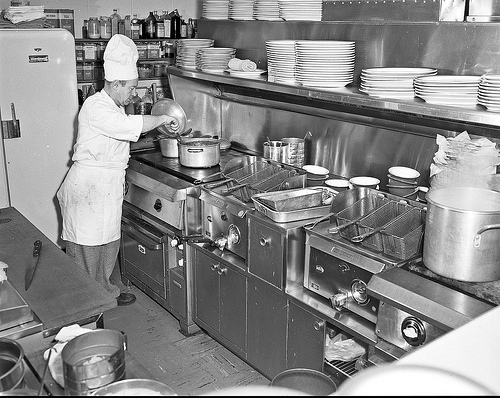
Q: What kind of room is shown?
A: It is a kitchen.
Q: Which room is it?
A: It is a kitchen.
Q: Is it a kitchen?
A: Yes, it is a kitchen.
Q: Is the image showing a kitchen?
A: Yes, it is showing a kitchen.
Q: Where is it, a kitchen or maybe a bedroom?
A: It is a kitchen.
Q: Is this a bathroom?
A: No, it is a kitchen.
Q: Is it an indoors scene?
A: Yes, it is indoors.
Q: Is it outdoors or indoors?
A: It is indoors.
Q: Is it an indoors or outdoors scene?
A: It is indoors.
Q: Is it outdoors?
A: No, it is indoors.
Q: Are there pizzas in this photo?
A: No, there are no pizzas.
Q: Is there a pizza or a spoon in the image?
A: No, there are no pizzas or spoons.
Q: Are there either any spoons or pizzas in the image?
A: No, there are no pizzas or spoons.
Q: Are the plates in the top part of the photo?
A: Yes, the plates are in the top of the image.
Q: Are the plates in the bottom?
A: No, the plates are in the top of the image.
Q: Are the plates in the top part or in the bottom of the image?
A: The plates are in the top of the image.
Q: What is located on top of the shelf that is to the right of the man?
A: The plates are on top of the shelf.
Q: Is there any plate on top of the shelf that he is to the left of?
A: Yes, there are plates on top of the shelf.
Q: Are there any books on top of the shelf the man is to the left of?
A: No, there are plates on top of the shelf.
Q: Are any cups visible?
A: No, there are no cups.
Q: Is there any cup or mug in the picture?
A: No, there are no cups or mugs.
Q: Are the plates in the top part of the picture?
A: Yes, the plates are in the top of the image.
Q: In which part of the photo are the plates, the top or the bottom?
A: The plates are in the top of the image.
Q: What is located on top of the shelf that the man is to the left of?
A: The plates are on top of the shelf.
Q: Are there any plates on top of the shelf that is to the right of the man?
A: Yes, there are plates on top of the shelf.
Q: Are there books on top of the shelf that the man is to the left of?
A: No, there are plates on top of the shelf.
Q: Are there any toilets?
A: No, there are no toilets.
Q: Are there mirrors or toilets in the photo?
A: No, there are no toilets or mirrors.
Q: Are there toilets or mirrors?
A: No, there are no toilets or mirrors.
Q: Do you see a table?
A: Yes, there is a table.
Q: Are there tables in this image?
A: Yes, there is a table.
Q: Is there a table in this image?
A: Yes, there is a table.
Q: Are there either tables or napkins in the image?
A: Yes, there is a table.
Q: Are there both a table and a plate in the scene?
A: Yes, there are both a table and a plate.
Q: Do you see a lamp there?
A: No, there are no lamps.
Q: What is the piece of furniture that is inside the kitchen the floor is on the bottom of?
A: The piece of furniture is a table.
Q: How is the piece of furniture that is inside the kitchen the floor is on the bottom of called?
A: The piece of furniture is a table.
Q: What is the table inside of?
A: The table is inside the kitchen.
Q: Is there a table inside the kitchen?
A: Yes, there is a table inside the kitchen.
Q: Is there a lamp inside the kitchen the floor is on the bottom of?
A: No, there is a table inside the kitchen.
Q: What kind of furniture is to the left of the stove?
A: The piece of furniture is a table.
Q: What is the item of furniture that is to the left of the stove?
A: The piece of furniture is a table.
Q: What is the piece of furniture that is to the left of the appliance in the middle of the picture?
A: The piece of furniture is a table.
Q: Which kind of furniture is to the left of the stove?
A: The piece of furniture is a table.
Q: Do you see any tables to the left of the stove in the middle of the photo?
A: Yes, there is a table to the left of the stove.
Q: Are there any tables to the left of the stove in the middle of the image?
A: Yes, there is a table to the left of the stove.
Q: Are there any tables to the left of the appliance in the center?
A: Yes, there is a table to the left of the stove.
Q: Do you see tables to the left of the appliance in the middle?
A: Yes, there is a table to the left of the stove.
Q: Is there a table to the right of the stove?
A: No, the table is to the left of the stove.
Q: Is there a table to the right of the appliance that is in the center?
A: No, the table is to the left of the stove.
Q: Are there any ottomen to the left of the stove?
A: No, there is a table to the left of the stove.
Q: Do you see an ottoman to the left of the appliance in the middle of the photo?
A: No, there is a table to the left of the stove.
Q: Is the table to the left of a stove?
A: Yes, the table is to the left of a stove.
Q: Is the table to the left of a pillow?
A: No, the table is to the left of a stove.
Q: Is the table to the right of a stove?
A: No, the table is to the left of a stove.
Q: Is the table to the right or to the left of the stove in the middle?
A: The table is to the left of the stove.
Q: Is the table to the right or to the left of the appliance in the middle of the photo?
A: The table is to the left of the stove.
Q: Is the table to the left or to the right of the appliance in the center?
A: The table is to the left of the stove.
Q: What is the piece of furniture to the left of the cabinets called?
A: The piece of furniture is a table.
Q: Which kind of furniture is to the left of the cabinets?
A: The piece of furniture is a table.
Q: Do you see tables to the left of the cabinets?
A: Yes, there is a table to the left of the cabinets.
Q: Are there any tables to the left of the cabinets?
A: Yes, there is a table to the left of the cabinets.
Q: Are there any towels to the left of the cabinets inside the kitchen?
A: No, there is a table to the left of the cabinets.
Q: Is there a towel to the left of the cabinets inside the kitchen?
A: No, there is a table to the left of the cabinets.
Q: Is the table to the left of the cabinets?
A: Yes, the table is to the left of the cabinets.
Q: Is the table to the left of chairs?
A: No, the table is to the left of the cabinets.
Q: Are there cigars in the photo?
A: No, there are no cigars.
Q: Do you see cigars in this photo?
A: No, there are no cigars.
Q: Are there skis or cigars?
A: No, there are no cigars or skis.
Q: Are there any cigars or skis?
A: No, there are no cigars or skis.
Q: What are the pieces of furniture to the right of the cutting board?
A: The pieces of furniture are cabinets.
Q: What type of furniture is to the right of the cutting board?
A: The pieces of furniture are cabinets.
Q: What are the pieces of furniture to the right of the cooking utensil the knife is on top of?
A: The pieces of furniture are cabinets.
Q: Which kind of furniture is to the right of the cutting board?
A: The pieces of furniture are cabinets.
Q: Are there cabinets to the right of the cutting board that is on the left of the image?
A: Yes, there are cabinets to the right of the cutting board.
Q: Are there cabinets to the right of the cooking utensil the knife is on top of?
A: Yes, there are cabinets to the right of the cutting board.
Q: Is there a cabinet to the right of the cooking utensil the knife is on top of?
A: Yes, there are cabinets to the right of the cutting board.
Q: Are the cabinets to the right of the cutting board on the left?
A: Yes, the cabinets are to the right of the cutting board.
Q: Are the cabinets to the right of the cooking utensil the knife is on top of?
A: Yes, the cabinets are to the right of the cutting board.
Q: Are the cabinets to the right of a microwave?
A: No, the cabinets are to the right of the cutting board.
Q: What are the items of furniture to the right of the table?
A: The pieces of furniture are cabinets.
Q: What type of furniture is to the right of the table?
A: The pieces of furniture are cabinets.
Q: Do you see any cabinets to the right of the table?
A: Yes, there are cabinets to the right of the table.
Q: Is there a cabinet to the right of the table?
A: Yes, there are cabinets to the right of the table.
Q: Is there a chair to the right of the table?
A: No, there are cabinets to the right of the table.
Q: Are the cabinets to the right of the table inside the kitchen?
A: Yes, the cabinets are to the right of the table.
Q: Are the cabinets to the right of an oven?
A: No, the cabinets are to the right of the table.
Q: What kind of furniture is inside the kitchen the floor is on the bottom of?
A: The pieces of furniture are cabinets.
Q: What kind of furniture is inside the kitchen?
A: The pieces of furniture are cabinets.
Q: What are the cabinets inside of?
A: The cabinets are inside the kitchen.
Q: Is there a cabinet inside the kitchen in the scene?
A: Yes, there are cabinets inside the kitchen.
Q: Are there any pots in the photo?
A: Yes, there is a pot.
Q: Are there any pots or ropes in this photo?
A: Yes, there is a pot.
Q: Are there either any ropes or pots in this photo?
A: Yes, there is a pot.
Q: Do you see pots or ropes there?
A: Yes, there is a pot.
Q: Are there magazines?
A: No, there are no magazines.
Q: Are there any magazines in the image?
A: No, there are no magazines.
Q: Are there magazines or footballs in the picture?
A: No, there are no magazines or footballs.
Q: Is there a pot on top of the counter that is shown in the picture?
A: Yes, there is a pot on top of the counter.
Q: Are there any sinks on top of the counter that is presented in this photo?
A: No, there is a pot on top of the counter.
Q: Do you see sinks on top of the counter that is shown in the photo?
A: No, there is a pot on top of the counter.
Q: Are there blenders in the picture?
A: No, there are no blenders.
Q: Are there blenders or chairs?
A: No, there are no blenders or chairs.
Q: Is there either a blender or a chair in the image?
A: No, there are no blenders or chairs.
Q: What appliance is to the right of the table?
A: The appliance is a stove.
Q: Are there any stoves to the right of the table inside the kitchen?
A: Yes, there is a stove to the right of the table.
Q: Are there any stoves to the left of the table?
A: No, the stove is to the right of the table.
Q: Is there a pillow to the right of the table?
A: No, there is a stove to the right of the table.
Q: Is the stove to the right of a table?
A: Yes, the stove is to the right of a table.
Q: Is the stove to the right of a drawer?
A: No, the stove is to the right of a table.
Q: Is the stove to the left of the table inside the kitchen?
A: No, the stove is to the right of the table.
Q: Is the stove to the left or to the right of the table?
A: The stove is to the right of the table.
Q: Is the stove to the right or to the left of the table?
A: The stove is to the right of the table.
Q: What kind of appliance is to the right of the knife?
A: The appliance is a stove.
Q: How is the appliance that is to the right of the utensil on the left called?
A: The appliance is a stove.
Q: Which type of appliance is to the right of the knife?
A: The appliance is a stove.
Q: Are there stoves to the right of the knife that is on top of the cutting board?
A: Yes, there is a stove to the right of the knife.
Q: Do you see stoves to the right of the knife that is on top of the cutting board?
A: Yes, there is a stove to the right of the knife.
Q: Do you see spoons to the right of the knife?
A: No, there is a stove to the right of the knife.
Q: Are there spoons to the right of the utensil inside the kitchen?
A: No, there is a stove to the right of the knife.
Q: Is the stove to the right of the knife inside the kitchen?
A: Yes, the stove is to the right of the knife.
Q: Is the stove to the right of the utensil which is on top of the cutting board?
A: Yes, the stove is to the right of the knife.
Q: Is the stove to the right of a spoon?
A: No, the stove is to the right of the knife.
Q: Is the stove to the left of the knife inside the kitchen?
A: No, the stove is to the right of the knife.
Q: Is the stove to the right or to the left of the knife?
A: The stove is to the right of the knife.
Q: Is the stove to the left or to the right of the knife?
A: The stove is to the right of the knife.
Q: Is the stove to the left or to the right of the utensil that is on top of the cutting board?
A: The stove is to the right of the knife.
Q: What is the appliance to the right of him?
A: The appliance is a stove.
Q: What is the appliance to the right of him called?
A: The appliance is a stove.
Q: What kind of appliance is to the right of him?
A: The appliance is a stove.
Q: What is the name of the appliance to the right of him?
A: The appliance is a stove.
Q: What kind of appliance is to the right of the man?
A: The appliance is a stove.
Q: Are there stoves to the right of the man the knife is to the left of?
A: Yes, there is a stove to the right of the man.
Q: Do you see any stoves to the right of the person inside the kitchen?
A: Yes, there is a stove to the right of the man.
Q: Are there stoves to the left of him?
A: No, the stove is to the right of the man.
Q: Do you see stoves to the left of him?
A: No, the stove is to the right of the man.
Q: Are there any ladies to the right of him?
A: No, there is a stove to the right of the man.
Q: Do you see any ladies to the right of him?
A: No, there is a stove to the right of the man.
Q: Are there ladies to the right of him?
A: No, there is a stove to the right of the man.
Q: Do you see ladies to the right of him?
A: No, there is a stove to the right of the man.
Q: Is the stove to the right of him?
A: Yes, the stove is to the right of a man.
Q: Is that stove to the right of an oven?
A: No, the stove is to the right of a man.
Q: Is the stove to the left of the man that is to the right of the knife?
A: No, the stove is to the right of the man.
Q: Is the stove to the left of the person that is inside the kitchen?
A: No, the stove is to the right of the man.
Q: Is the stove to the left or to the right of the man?
A: The stove is to the right of the man.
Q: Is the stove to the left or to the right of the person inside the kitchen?
A: The stove is to the right of the man.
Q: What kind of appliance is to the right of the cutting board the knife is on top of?
A: The appliance is a stove.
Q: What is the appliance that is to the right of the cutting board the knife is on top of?
A: The appliance is a stove.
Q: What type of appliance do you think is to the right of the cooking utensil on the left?
A: The appliance is a stove.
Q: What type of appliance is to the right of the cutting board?
A: The appliance is a stove.